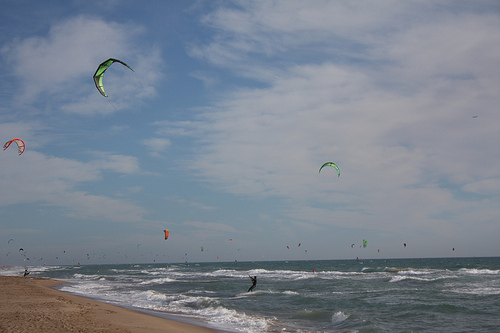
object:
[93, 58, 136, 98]
kite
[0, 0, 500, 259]
sky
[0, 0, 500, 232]
clouds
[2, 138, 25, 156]
kite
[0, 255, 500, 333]
water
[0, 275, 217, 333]
beach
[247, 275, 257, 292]
person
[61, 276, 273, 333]
waves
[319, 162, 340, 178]
kite